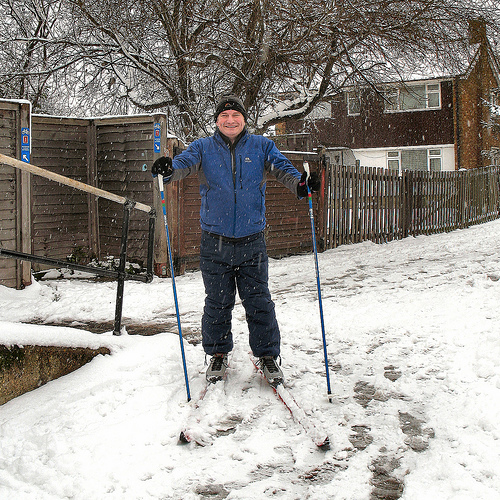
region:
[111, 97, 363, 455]
a man standing on some skis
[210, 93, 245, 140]
the head of a man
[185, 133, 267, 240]
the torso of a man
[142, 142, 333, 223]
the jacket of a man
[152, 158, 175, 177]
the glove of a man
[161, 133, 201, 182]
the right arm of a man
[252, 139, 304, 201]
the left arm of a man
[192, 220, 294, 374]
the pair of snow pants of a man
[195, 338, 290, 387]
a pair of snow shoes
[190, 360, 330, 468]
a pair of black skis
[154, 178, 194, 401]
a long blue and white trekking pole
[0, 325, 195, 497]
a section of white snow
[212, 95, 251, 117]
a man's gray and black cap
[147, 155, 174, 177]
a black glove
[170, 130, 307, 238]
a man's blue jacket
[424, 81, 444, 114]
a window of a home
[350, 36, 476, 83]
part of a roof of a home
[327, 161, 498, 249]
part of a long wooden fence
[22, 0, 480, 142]
part of a large snow covered tree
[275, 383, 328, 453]
part of a long ski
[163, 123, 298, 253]
THE MAN IS WEARING A BLUE JACKET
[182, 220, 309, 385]
THE MAN IS WEARING BLUE PANTS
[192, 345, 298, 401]
THE MAN IS WEARING GREY BOOTS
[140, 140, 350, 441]
THE MAN IS HOLDING POLES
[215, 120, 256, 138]
THE MAN IS SMILING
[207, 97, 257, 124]
THE HAT IS BLACK AND GREY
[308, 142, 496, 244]
THE FENCE IS WOODEN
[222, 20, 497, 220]
THE HOUSE IS BRICK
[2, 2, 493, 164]
THE OAK TREE IS LARGE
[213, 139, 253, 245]
THE JACKET HAS A ZIPPER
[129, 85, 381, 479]
This is a person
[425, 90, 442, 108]
Pane of a window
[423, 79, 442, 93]
Pane of a window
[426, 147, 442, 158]
Pane of a window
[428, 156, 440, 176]
Pane of a window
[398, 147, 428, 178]
Pane of a window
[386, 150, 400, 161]
Pane of a window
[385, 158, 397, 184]
Pane of a window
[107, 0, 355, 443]
man is on skis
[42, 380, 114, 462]
snow on the ground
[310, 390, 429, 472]
footprints in the snow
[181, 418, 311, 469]
the snow is white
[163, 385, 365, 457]
snow on the skis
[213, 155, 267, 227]
the coat is blue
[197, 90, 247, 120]
hat on the head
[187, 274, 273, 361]
the pants are dark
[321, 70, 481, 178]
house behind the fence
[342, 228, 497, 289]
the snow is scattered